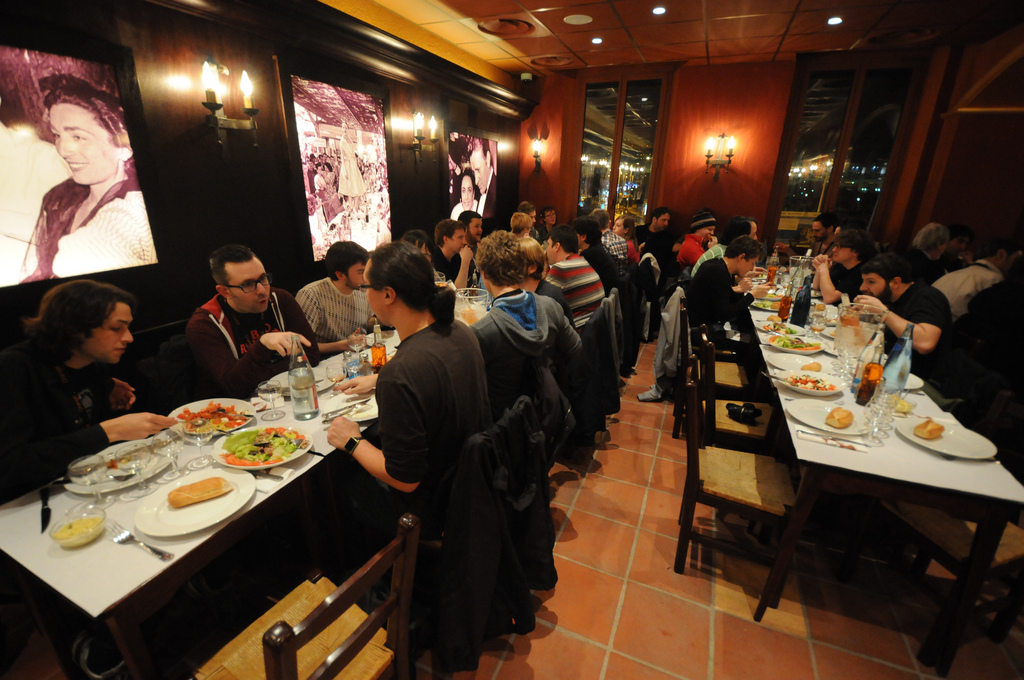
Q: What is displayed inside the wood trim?
A: Photos.